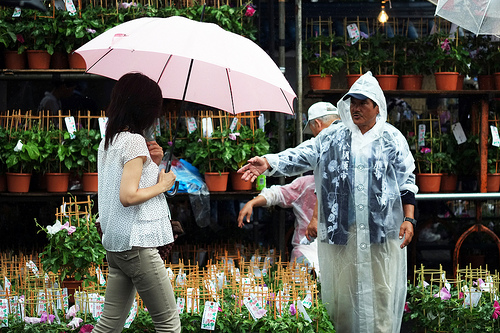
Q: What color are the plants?
A: Green.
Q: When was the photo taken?
A: Daytime.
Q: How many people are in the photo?
A: Four.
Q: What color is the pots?
A: Brown.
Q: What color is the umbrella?
A: Light Pink.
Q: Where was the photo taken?
A: Plant Shop.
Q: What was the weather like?
A: Raining.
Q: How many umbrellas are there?
A: One.